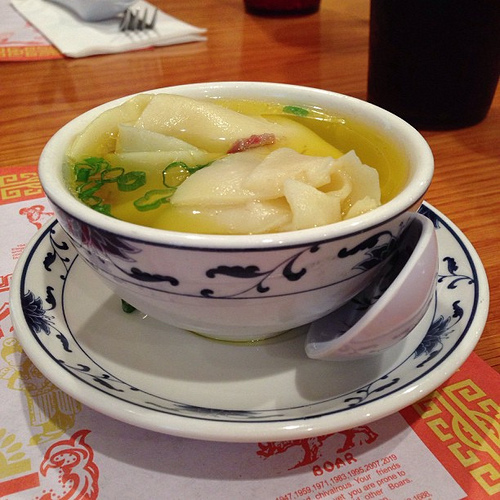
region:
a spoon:
[366, 266, 440, 320]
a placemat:
[321, 463, 420, 497]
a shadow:
[143, 450, 228, 487]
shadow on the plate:
[150, 337, 220, 389]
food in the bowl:
[211, 164, 289, 219]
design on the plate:
[420, 310, 464, 362]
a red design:
[29, 436, 105, 498]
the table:
[56, 63, 128, 99]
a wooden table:
[438, 138, 487, 204]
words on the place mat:
[292, 448, 381, 476]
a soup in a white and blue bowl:
[36, 79, 436, 339]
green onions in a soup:
[73, 152, 208, 214]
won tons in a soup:
[73, 90, 380, 224]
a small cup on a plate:
[305, 215, 437, 365]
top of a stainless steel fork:
[114, 9, 159, 29]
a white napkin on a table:
[7, 0, 209, 60]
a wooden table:
[1, 0, 498, 375]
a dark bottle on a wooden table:
[368, 0, 496, 132]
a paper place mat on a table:
[1, 161, 498, 498]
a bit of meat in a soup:
[229, 133, 275, 155]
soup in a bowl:
[89, 106, 328, 242]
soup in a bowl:
[59, 47, 444, 264]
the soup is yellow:
[114, 167, 202, 234]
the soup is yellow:
[274, 116, 373, 214]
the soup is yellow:
[184, 87, 365, 172]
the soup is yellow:
[62, 144, 260, 251]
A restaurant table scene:
[0, 0, 498, 497]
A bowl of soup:
[36, 79, 436, 345]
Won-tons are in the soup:
[66, 90, 384, 234]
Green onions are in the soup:
[67, 157, 189, 211]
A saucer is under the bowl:
[6, 199, 491, 444]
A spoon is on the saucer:
[304, 210, 442, 362]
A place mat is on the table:
[0, 163, 498, 498]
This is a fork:
[114, 5, 162, 35]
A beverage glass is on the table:
[364, 1, 499, 133]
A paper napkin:
[10, 1, 208, 59]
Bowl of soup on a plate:
[2, 75, 492, 446]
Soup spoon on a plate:
[298, 205, 443, 365]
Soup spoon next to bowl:
[301, 197, 441, 368]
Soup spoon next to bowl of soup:
[300, 208, 440, 370]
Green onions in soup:
[67, 97, 314, 219]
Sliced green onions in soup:
[70, 101, 309, 223]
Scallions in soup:
[70, 102, 310, 223]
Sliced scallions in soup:
[67, 97, 310, 222]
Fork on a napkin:
[102, 0, 166, 34]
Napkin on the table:
[5, 0, 214, 64]